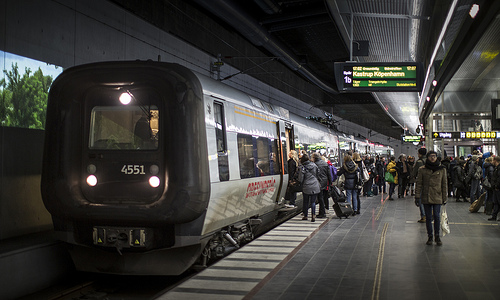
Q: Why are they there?
A: To get on the train.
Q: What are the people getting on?
A: Train.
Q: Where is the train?
A: On the tracks.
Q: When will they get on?
A: Now.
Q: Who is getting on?
A: People.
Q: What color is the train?
A: Silver.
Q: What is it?
A: Train.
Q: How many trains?
A: 1.